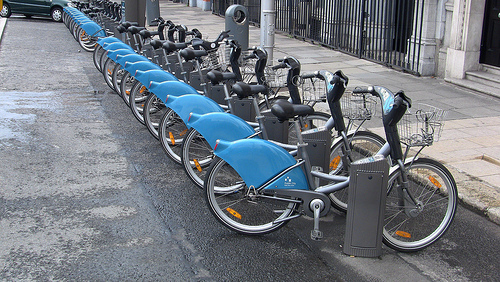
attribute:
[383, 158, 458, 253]
wheel — front wheel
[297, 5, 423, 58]
grills — metallic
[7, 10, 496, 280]
road — clean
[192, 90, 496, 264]
bicycles — metalic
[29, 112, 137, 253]
road — grey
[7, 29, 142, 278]
road — paved, tarmacked